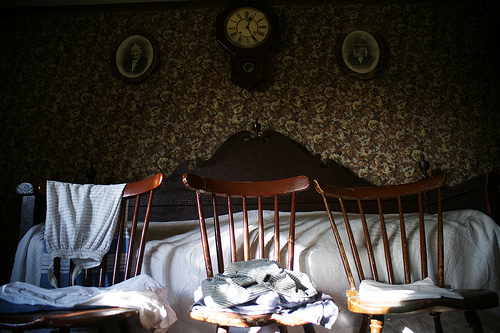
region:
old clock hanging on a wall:
[215, 12, 280, 96]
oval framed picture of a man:
[335, 24, 387, 82]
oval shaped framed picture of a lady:
[108, 26, 160, 83]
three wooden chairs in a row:
[28, 162, 473, 316]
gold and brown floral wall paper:
[166, 92, 206, 137]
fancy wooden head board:
[151, 115, 370, 175]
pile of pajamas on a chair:
[182, 247, 344, 323]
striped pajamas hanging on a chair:
[34, 174, 163, 281]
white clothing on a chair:
[2, 275, 169, 319]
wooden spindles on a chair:
[343, 201, 448, 260]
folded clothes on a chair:
[350, 267, 463, 312]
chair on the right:
[314, 168, 464, 331]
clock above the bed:
[207, 0, 291, 94]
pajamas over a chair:
[36, 173, 124, 267]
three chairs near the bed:
[4, 172, 494, 332]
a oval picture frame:
[112, 27, 159, 85]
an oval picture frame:
[332, 22, 387, 82]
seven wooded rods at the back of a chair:
[194, 192, 303, 276]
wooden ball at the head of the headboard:
[247, 117, 264, 138]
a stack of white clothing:
[189, 259, 339, 330]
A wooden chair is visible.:
[314, 158, 426, 326]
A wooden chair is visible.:
[282, 75, 436, 306]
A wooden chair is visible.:
[325, 197, 399, 324]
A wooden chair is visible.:
[347, 147, 468, 304]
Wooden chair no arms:
[169, 155, 311, 322]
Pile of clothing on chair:
[200, 243, 321, 325]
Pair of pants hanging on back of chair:
[37, 170, 119, 271]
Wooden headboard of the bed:
[104, 117, 474, 219]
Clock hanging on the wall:
[212, 4, 286, 86]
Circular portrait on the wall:
[334, 21, 389, 84]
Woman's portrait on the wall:
[107, 27, 159, 79]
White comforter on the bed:
[155, 221, 202, 283]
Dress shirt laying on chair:
[362, 267, 476, 307]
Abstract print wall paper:
[312, 77, 374, 160]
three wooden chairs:
[48, 158, 464, 328]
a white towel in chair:
[368, 274, 437, 304]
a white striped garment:
[43, 183, 125, 256]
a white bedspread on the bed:
[307, 228, 324, 261]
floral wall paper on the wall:
[352, 106, 437, 156]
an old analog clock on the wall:
[205, 2, 292, 88]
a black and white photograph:
[104, 22, 190, 97]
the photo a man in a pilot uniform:
[332, 24, 408, 85]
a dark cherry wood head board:
[229, 128, 350, 180]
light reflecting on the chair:
[358, 285, 405, 315]